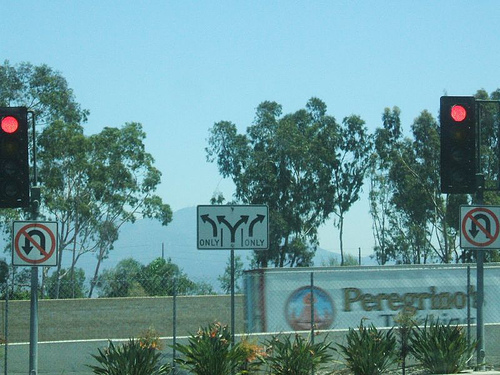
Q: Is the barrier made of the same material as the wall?
A: Yes, both the barrier and the wall are made of cement.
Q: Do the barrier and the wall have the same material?
A: Yes, both the barrier and the wall are made of cement.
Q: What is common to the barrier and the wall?
A: The material, both the barrier and the wall are concrete.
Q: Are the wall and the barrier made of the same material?
A: Yes, both the wall and the barrier are made of concrete.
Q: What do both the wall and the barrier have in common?
A: The material, both the wall and the barrier are concrete.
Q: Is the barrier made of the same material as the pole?
A: No, the barrier is made of concrete and the pole is made of metal.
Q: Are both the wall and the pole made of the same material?
A: No, the wall is made of concrete and the pole is made of metal.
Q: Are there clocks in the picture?
A: No, there are no clocks.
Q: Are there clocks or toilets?
A: No, there are no clocks or toilets.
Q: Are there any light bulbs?
A: No, there are no light bulbs.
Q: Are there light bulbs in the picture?
A: No, there are no light bulbs.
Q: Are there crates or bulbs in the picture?
A: No, there are no bulbs or crates.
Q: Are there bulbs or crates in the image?
A: No, there are no bulbs or crates.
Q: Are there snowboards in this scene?
A: No, there are no snowboards.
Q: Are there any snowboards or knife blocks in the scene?
A: No, there are no snowboards or knife blocks.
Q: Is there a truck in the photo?
A: Yes, there is a truck.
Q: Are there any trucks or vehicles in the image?
A: Yes, there is a truck.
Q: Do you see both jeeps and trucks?
A: No, there is a truck but no jeeps.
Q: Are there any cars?
A: No, there are no cars.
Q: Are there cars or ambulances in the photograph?
A: No, there are no cars or ambulances.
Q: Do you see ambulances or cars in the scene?
A: No, there are no cars or ambulances.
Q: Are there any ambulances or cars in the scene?
A: No, there are no cars or ambulances.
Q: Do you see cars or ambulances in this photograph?
A: No, there are no cars or ambulances.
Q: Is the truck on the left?
A: Yes, the truck is on the left of the image.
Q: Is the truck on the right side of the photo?
A: No, the truck is on the left of the image.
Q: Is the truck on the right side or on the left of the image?
A: The truck is on the left of the image.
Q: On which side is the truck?
A: The truck is on the left of the image.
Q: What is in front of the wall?
A: The road is in front of the wall.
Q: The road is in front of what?
A: The road is in front of the wall.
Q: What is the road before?
A: The road is in front of the wall.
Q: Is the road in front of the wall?
A: Yes, the road is in front of the wall.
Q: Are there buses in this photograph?
A: No, there are no buses.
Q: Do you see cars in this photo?
A: No, there are no cars.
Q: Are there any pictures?
A: No, there are no pictures.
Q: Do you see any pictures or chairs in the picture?
A: No, there are no pictures or chairs.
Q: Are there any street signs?
A: Yes, there is a street sign.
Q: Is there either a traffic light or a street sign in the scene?
A: Yes, there is a street sign.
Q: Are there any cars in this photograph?
A: No, there are no cars.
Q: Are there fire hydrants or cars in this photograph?
A: No, there are no cars or fire hydrants.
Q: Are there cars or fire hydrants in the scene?
A: No, there are no cars or fire hydrants.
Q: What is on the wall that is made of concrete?
A: The street sign is on the wall.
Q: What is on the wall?
A: The street sign is on the wall.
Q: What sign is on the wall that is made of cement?
A: The sign is a street sign.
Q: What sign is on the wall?
A: The sign is a street sign.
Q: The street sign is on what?
A: The street sign is on the wall.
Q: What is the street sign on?
A: The street sign is on the wall.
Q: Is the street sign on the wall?
A: Yes, the street sign is on the wall.